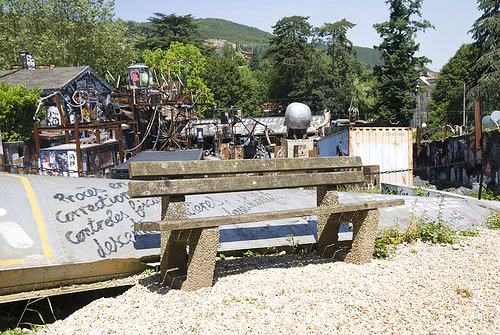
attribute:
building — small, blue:
[6, 58, 113, 131]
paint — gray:
[0, 172, 499, 270]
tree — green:
[271, 19, 334, 78]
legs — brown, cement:
[159, 220, 382, 290]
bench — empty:
[110, 153, 400, 283]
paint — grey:
[350, 142, 405, 165]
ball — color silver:
[279, 95, 326, 138]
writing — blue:
[51, 180, 159, 255]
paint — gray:
[34, 177, 70, 234]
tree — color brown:
[366, 0, 436, 134]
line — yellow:
[10, 168, 74, 284]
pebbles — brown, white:
[42, 234, 494, 334]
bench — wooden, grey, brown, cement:
[128, 162, 412, 290]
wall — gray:
[19, 206, 107, 239]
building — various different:
[171, 107, 343, 165]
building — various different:
[0, 50, 149, 173]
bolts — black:
[161, 172, 172, 188]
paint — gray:
[449, 201, 472, 214]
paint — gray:
[268, 199, 321, 209]